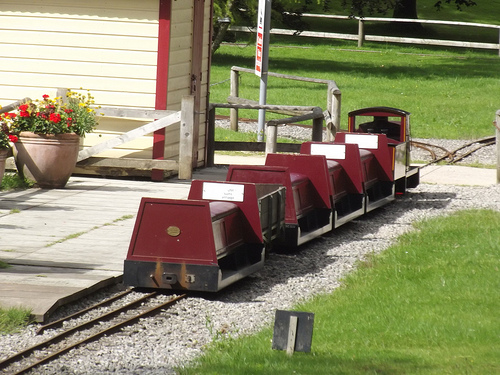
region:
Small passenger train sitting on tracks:
[121, 105, 421, 296]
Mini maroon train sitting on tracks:
[123, 104, 420, 294]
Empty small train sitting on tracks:
[122, 107, 420, 295]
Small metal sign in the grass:
[271, 310, 315, 355]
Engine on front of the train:
[345, 106, 422, 191]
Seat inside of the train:
[189, 201, 252, 259]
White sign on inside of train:
[201, 182, 244, 203]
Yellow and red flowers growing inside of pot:
[2, 84, 104, 189]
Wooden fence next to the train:
[211, 66, 342, 155]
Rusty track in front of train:
[411, 139, 455, 165]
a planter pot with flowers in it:
[1, 89, 106, 187]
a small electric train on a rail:
[118, 105, 419, 293]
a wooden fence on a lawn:
[227, 8, 499, 50]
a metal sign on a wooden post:
[273, 309, 314, 354]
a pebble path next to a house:
[0, 117, 499, 373]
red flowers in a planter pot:
[4, 94, 71, 143]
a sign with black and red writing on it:
[253, 1, 265, 76]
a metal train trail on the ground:
[0, 113, 495, 373]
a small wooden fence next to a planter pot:
[0, 87, 193, 182]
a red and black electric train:
[122, 105, 419, 292]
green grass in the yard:
[383, 252, 498, 339]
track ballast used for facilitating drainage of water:
[121, 345, 168, 366]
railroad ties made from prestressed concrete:
[62, 333, 77, 338]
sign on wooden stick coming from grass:
[268, 308, 309, 352]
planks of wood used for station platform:
[1, 191, 124, 271]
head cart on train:
[348, 102, 419, 186]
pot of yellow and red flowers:
[1, 85, 97, 178]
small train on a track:
[69, 131, 438, 266]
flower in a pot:
[1, 102, 109, 198]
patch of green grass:
[352, 312, 379, 338]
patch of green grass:
[382, 337, 431, 373]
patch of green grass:
[293, 352, 325, 369]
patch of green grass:
[385, 273, 414, 298]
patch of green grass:
[422, 334, 464, 363]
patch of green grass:
[389, 265, 416, 290]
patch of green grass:
[446, 253, 475, 278]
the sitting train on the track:
[122, 106, 420, 289]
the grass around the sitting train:
[0, 0, 499, 374]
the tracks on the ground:
[0, 110, 498, 374]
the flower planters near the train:
[0, 85, 105, 192]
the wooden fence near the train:
[0, 8, 497, 180]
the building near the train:
[0, 0, 214, 182]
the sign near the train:
[253, 0, 273, 142]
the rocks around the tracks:
[0, 114, 498, 373]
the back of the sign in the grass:
[272, 308, 314, 356]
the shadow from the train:
[130, 190, 455, 302]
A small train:
[125, 106, 433, 280]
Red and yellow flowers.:
[1, 85, 99, 166]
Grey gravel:
[8, 114, 498, 371]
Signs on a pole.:
[247, 1, 272, 143]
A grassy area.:
[202, 26, 498, 373]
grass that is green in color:
[418, 83, 495, 148]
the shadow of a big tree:
[361, 43, 449, 114]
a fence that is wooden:
[362, 6, 497, 63]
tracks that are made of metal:
[64, 315, 125, 362]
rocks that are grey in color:
[122, 321, 184, 365]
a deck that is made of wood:
[30, 202, 152, 307]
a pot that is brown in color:
[5, 131, 89, 198]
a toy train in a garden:
[116, 97, 431, 315]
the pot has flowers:
[2, 78, 105, 193]